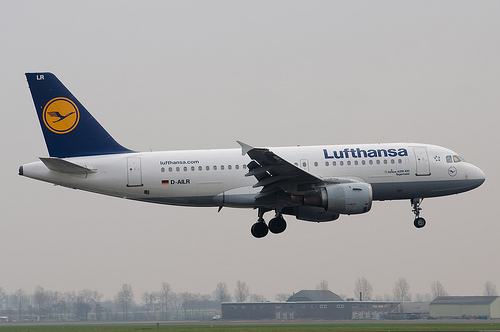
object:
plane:
[17, 72, 484, 238]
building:
[218, 285, 497, 324]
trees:
[15, 284, 242, 321]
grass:
[0, 322, 500, 331]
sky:
[20, 10, 486, 47]